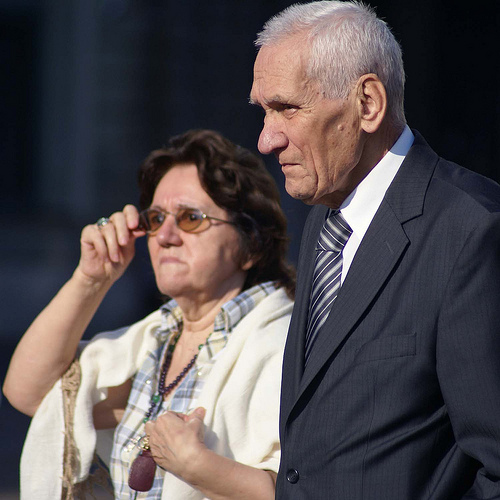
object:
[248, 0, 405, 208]
head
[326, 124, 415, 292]
dress shirt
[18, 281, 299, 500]
coat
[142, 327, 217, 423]
necklace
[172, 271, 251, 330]
neck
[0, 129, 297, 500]
woman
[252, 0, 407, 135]
hair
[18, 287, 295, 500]
shawl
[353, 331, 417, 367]
pocket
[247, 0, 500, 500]
man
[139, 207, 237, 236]
glasses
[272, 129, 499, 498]
coat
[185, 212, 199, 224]
eyes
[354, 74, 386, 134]
ear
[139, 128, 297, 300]
hair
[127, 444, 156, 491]
keychain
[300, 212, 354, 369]
tie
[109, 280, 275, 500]
shirt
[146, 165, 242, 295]
face